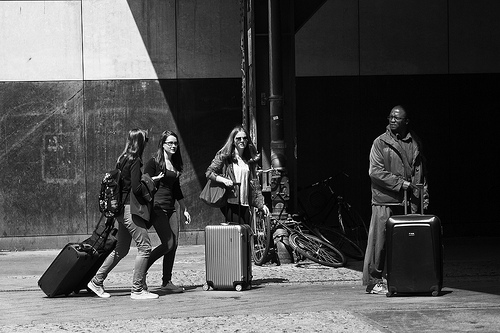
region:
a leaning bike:
[311, 172, 368, 242]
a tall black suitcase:
[387, 180, 442, 297]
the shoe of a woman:
[130, 290, 160, 298]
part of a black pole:
[263, 0, 288, 175]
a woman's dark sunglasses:
[234, 136, 250, 142]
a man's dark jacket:
[367, 125, 433, 206]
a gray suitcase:
[204, 180, 254, 291]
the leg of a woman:
[117, 210, 156, 289]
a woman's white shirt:
[234, 148, 254, 209]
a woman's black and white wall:
[82, 0, 178, 236]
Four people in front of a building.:
[4, 82, 485, 308]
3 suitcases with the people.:
[15, 146, 486, 314]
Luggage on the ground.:
[174, 180, 247, 331]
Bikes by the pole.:
[230, 176, 361, 283]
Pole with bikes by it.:
[227, 4, 348, 261]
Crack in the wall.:
[35, 12, 229, 254]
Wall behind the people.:
[42, 22, 498, 284]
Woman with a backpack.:
[67, 169, 135, 244]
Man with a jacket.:
[366, 89, 451, 206]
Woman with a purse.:
[195, 135, 257, 238]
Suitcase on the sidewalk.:
[145, 184, 366, 306]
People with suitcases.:
[22, 102, 476, 314]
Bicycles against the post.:
[242, 131, 359, 276]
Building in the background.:
[45, 46, 439, 301]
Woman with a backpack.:
[58, 112, 217, 304]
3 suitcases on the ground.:
[3, 220, 488, 312]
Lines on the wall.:
[59, 25, 171, 212]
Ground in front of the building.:
[92, 279, 270, 331]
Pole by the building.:
[225, 12, 362, 234]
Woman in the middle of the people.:
[200, 114, 320, 304]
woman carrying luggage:
[81, 127, 159, 300]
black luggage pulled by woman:
[40, 207, 111, 293]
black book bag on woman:
[92, 155, 132, 215]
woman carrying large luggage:
[197, 122, 268, 282]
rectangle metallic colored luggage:
[202, 180, 248, 287]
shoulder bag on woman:
[195, 155, 230, 200]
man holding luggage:
[356, 100, 426, 300]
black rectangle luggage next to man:
[385, 180, 445, 295]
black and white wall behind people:
[0, 0, 495, 250]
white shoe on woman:
[127, 287, 157, 300]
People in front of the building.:
[92, 91, 489, 312]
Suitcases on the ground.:
[43, 192, 498, 274]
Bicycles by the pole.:
[197, 210, 397, 274]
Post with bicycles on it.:
[229, 15, 349, 285]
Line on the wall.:
[36, 25, 167, 297]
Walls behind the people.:
[48, 25, 379, 276]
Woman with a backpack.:
[77, 111, 149, 222]